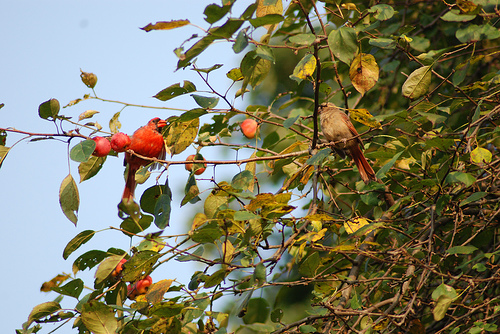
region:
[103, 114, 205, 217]
a apple hanging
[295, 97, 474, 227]
a bird perched into the tree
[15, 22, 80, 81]
the nice blue sky in the scene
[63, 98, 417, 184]
two birds facing each other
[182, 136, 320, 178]
a branch hanging from the tree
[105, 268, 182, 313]
a group of apples on the tree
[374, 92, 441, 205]
burnt flowers on the tree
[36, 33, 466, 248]
a nice fall day portrayed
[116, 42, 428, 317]
what a lovel day for some apples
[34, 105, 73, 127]
a leaf that is hanging on a branch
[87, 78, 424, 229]
birds perched on branch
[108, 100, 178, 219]
the bird is red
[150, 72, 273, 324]
the leaves are green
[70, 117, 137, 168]
the fruits are red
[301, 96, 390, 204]
the bird is brown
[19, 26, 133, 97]
the sky is blue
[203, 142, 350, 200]
the branch is brown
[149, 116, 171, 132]
the beak is red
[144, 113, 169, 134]
bird's face is black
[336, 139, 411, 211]
the tail is brown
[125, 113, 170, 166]
red bird sitting in tree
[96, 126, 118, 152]
red berries in tree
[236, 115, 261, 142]
red berry in tree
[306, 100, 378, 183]
brown bird sitting in tree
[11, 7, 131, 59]
white clouds against blue sky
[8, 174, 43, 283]
white clouds against blue sky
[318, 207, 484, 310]
brown branches with green leaves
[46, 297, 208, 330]
brown branches with green leaves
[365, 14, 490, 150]
brown branches with green leaves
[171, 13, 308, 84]
brown branches with green leaves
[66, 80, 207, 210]
a red bird in a tree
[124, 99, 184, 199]
a red bird on a branch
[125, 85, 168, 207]
a red bird on a tree branch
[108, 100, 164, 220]
red bird sitting in tree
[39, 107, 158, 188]
fruit on the tree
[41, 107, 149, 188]
fruit on the branch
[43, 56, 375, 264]
two bird sitting in tree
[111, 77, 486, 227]
two birds sitting on branch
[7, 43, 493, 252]
two birds sitting during the day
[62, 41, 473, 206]
two birds sitting on thin branches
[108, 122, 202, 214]
red bird on branch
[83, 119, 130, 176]
red fruit on branch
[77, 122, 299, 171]
brown branch with leaves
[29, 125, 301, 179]
brown branch and fruit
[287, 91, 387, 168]
yellow and brown bird on branch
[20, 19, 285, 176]
blue sky in background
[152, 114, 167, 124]
black eyes of bird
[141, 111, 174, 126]
red beak on bird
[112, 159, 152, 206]
tail of bird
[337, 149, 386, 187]
tail of bird